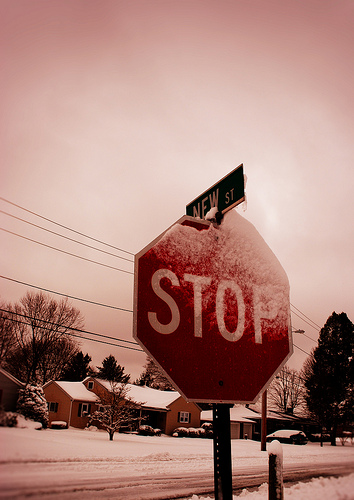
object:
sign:
[133, 215, 296, 402]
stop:
[150, 267, 279, 350]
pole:
[212, 402, 236, 499]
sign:
[185, 163, 245, 217]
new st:
[191, 183, 236, 218]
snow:
[150, 212, 294, 336]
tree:
[303, 335, 348, 448]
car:
[268, 427, 309, 445]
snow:
[268, 429, 305, 441]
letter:
[216, 280, 247, 342]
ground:
[2, 425, 353, 499]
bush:
[0, 409, 14, 428]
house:
[40, 376, 101, 430]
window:
[179, 416, 185, 423]